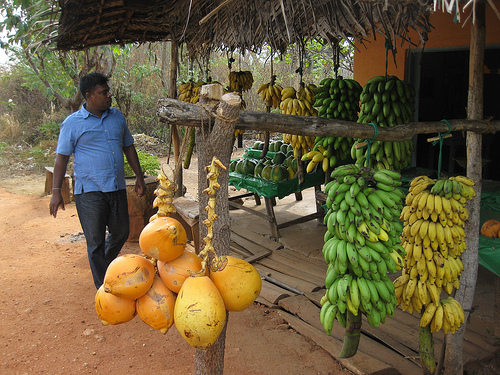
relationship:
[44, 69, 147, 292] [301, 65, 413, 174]
man looks food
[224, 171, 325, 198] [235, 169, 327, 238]
tarp on table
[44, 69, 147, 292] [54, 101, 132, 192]
man wears shirt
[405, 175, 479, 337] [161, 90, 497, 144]
bananas hang from trunk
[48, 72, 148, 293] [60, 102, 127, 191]
man wearing shirt